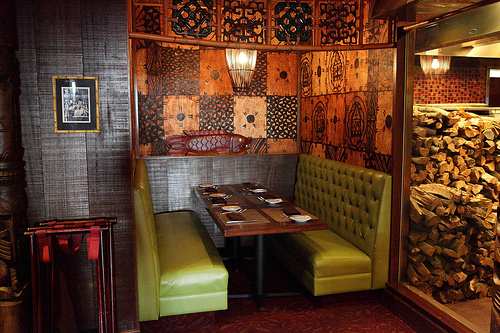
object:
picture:
[60, 86, 91, 124]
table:
[190, 182, 330, 313]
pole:
[254, 235, 265, 301]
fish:
[162, 129, 254, 157]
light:
[224, 48, 259, 92]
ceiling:
[416, 2, 500, 73]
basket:
[24, 216, 121, 333]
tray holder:
[24, 216, 118, 332]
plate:
[289, 214, 312, 223]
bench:
[128, 158, 231, 322]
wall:
[18, 2, 142, 333]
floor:
[75, 276, 433, 332]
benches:
[264, 152, 392, 299]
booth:
[193, 182, 328, 238]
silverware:
[225, 219, 259, 224]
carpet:
[143, 293, 439, 333]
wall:
[136, 156, 300, 251]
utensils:
[224, 220, 260, 227]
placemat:
[214, 208, 271, 226]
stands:
[96, 229, 110, 333]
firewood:
[407, 100, 498, 304]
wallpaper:
[132, 4, 389, 172]